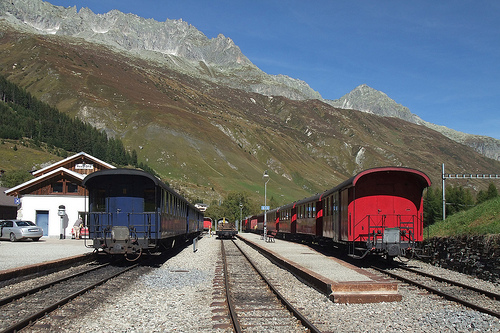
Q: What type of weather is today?
A: It is clear.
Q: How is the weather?
A: It is clear.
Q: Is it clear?
A: Yes, it is clear.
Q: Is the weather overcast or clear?
A: It is clear.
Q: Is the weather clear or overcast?
A: It is clear.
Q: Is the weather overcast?
A: No, it is clear.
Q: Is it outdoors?
A: Yes, it is outdoors.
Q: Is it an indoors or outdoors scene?
A: It is outdoors.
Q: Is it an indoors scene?
A: No, it is outdoors.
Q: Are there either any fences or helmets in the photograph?
A: No, there are no fences or helmets.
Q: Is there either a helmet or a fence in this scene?
A: No, there are no fences or helmets.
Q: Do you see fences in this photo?
A: No, there are no fences.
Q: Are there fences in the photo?
A: No, there are no fences.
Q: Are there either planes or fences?
A: No, there are no fences or planes.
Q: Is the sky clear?
A: Yes, the sky is clear.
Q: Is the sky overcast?
A: No, the sky is clear.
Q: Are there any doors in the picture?
A: Yes, there is a door.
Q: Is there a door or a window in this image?
A: Yes, there is a door.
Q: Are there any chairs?
A: No, there are no chairs.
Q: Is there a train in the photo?
A: Yes, there is a train.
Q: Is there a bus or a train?
A: Yes, there is a train.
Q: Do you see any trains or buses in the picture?
A: Yes, there is a train.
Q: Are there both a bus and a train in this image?
A: No, there is a train but no buses.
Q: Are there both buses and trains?
A: No, there is a train but no buses.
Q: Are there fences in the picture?
A: No, there are no fences.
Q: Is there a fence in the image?
A: No, there are no fences.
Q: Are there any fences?
A: No, there are no fences.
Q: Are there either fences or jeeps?
A: No, there are no fences or jeeps.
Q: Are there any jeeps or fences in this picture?
A: No, there are no fences or jeeps.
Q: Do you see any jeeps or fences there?
A: No, there are no fences or jeeps.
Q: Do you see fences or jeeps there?
A: No, there are no fences or jeeps.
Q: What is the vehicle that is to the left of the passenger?
A: The vehicle is a train.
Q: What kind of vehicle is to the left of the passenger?
A: The vehicle is a train.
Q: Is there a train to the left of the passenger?
A: Yes, there is a train to the left of the passenger.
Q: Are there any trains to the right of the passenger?
A: No, the train is to the left of the passenger.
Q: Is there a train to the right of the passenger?
A: No, the train is to the left of the passenger.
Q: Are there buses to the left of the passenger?
A: No, there is a train to the left of the passenger.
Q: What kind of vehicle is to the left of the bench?
A: The vehicle is a train.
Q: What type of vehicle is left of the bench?
A: The vehicle is a train.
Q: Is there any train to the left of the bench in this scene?
A: Yes, there is a train to the left of the bench.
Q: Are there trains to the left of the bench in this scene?
A: Yes, there is a train to the left of the bench.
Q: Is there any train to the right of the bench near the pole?
A: No, the train is to the left of the bench.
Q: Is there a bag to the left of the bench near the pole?
A: No, there is a train to the left of the bench.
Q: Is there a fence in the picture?
A: No, there are no fences.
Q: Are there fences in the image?
A: No, there are no fences.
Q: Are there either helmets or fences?
A: No, there are no fences or helmets.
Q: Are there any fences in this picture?
A: No, there are no fences.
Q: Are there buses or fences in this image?
A: No, there are no fences or buses.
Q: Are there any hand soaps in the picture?
A: No, there are no hand soaps.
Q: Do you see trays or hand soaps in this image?
A: No, there are no hand soaps or trays.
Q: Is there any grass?
A: Yes, there is grass.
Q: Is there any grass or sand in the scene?
A: Yes, there is grass.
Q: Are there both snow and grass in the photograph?
A: No, there is grass but no snow.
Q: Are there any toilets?
A: No, there are no toilets.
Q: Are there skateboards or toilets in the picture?
A: No, there are no toilets or skateboards.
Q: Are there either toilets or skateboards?
A: No, there are no toilets or skateboards.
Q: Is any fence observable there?
A: No, there are no fences.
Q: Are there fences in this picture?
A: No, there are no fences.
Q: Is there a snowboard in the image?
A: No, there are no snowboards.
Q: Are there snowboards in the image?
A: No, there are no snowboards.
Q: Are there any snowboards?
A: No, there are no snowboards.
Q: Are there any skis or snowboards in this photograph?
A: No, there are no snowboards or skis.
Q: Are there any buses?
A: No, there are no buses.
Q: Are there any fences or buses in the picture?
A: No, there are no buses or fences.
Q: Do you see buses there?
A: No, there are no buses.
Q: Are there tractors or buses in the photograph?
A: No, there are no buses or tractors.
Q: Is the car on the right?
A: No, the car is on the left of the image.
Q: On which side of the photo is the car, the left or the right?
A: The car is on the left of the image.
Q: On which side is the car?
A: The car is on the left of the image.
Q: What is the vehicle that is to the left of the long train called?
A: The vehicle is a car.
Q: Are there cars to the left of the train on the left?
A: Yes, there is a car to the left of the train.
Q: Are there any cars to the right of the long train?
A: No, the car is to the left of the train.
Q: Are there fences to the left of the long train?
A: No, there is a car to the left of the train.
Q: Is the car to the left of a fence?
A: No, the car is to the left of the train.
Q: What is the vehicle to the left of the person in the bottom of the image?
A: The vehicle is a car.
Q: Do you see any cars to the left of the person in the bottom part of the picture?
A: Yes, there is a car to the left of the person.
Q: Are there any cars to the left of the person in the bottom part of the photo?
A: Yes, there is a car to the left of the person.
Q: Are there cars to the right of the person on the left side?
A: No, the car is to the left of the person.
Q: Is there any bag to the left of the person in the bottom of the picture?
A: No, there is a car to the left of the person.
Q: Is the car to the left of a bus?
A: No, the car is to the left of the person.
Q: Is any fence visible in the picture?
A: No, there are no fences.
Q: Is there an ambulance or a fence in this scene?
A: No, there are no fences or ambulances.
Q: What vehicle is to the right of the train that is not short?
A: The vehicle is a train car.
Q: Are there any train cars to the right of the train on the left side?
A: Yes, there is a train car to the right of the train.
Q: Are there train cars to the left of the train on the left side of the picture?
A: No, the train car is to the right of the train.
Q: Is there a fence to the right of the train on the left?
A: No, there is a train car to the right of the train.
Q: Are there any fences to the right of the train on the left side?
A: No, there is a train car to the right of the train.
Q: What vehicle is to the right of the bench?
A: The vehicle is a train car.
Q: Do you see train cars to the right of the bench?
A: Yes, there is a train car to the right of the bench.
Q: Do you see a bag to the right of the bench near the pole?
A: No, there is a train car to the right of the bench.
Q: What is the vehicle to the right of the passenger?
A: The vehicle is a train car.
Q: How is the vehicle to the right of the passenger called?
A: The vehicle is a train car.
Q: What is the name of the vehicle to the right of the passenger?
A: The vehicle is a train car.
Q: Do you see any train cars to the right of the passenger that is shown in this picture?
A: Yes, there is a train car to the right of the passenger.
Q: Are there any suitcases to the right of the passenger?
A: No, there is a train car to the right of the passenger.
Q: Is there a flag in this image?
A: No, there are no flags.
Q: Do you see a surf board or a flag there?
A: No, there are no flags or surfboards.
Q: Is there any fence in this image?
A: No, there are no fences.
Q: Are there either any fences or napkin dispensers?
A: No, there are no fences or napkin dispensers.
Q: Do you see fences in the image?
A: No, there are no fences.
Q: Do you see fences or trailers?
A: No, there are no fences or trailers.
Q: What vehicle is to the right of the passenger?
A: The vehicle is a train car.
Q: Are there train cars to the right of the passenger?
A: Yes, there is a train car to the right of the passenger.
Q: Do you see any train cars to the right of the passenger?
A: Yes, there is a train car to the right of the passenger.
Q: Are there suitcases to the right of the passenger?
A: No, there is a train car to the right of the passenger.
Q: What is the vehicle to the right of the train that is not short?
A: The vehicle is a train car.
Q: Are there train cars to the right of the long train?
A: Yes, there is a train car to the right of the train.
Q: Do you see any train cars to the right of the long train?
A: Yes, there is a train car to the right of the train.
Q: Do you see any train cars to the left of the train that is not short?
A: No, the train car is to the right of the train.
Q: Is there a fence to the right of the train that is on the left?
A: No, there is a train car to the right of the train.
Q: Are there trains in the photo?
A: Yes, there is a train.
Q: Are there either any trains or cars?
A: Yes, there is a train.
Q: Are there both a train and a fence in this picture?
A: No, there is a train but no fences.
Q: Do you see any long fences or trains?
A: Yes, there is a long train.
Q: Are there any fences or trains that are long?
A: Yes, the train is long.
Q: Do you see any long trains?
A: Yes, there is a long train.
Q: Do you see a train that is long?
A: Yes, there is a train that is long.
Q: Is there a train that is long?
A: Yes, there is a train that is long.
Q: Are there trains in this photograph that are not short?
A: Yes, there is a long train.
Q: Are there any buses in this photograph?
A: No, there are no buses.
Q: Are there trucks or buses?
A: No, there are no buses or trucks.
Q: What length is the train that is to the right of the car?
A: The train is long.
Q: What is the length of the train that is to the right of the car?
A: The train is long.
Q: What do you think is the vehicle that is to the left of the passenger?
A: The vehicle is a train.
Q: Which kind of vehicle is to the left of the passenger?
A: The vehicle is a train.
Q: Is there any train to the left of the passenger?
A: Yes, there is a train to the left of the passenger.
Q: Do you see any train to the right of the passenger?
A: No, the train is to the left of the passenger.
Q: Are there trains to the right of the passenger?
A: No, the train is to the left of the passenger.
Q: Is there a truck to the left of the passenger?
A: No, there is a train to the left of the passenger.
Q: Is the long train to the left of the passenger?
A: Yes, the train is to the left of the passenger.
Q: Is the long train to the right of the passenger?
A: No, the train is to the left of the passenger.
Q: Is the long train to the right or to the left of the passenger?
A: The train is to the left of the passenger.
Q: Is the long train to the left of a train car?
A: Yes, the train is to the left of a train car.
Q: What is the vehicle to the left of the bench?
A: The vehicle is a train.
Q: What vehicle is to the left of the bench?
A: The vehicle is a train.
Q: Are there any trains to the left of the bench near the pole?
A: Yes, there is a train to the left of the bench.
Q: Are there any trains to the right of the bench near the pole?
A: No, the train is to the left of the bench.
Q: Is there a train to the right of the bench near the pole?
A: No, the train is to the left of the bench.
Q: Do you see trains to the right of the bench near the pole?
A: No, the train is to the left of the bench.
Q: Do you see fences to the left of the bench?
A: No, there is a train to the left of the bench.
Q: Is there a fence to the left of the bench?
A: No, there is a train to the left of the bench.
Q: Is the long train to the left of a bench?
A: Yes, the train is to the left of a bench.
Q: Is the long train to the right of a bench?
A: No, the train is to the left of a bench.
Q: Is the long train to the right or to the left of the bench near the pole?
A: The train is to the left of the bench.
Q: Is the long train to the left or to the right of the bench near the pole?
A: The train is to the left of the bench.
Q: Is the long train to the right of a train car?
A: No, the train is to the left of a train car.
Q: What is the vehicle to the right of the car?
A: The vehicle is a train.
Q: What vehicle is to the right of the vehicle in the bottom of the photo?
A: The vehicle is a train.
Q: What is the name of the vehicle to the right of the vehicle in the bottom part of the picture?
A: The vehicle is a train.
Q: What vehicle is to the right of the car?
A: The vehicle is a train.